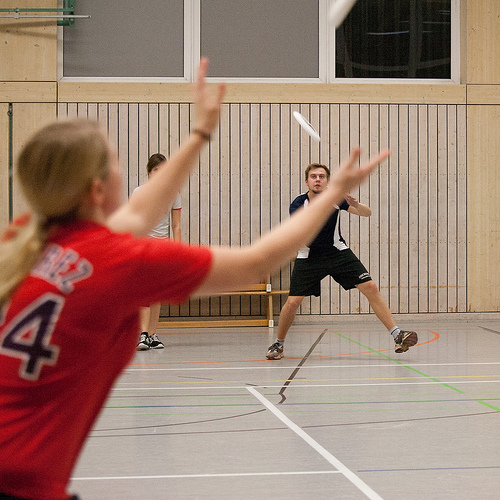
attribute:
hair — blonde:
[59, 188, 80, 195]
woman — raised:
[85, 68, 228, 192]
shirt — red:
[1, 315, 141, 421]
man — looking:
[296, 156, 336, 199]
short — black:
[279, 247, 356, 303]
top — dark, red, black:
[316, 199, 348, 253]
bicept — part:
[356, 183, 381, 213]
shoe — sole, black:
[408, 326, 418, 351]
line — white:
[261, 382, 293, 434]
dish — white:
[291, 101, 325, 149]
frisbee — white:
[308, 104, 329, 126]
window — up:
[170, 12, 359, 86]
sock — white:
[390, 319, 408, 333]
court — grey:
[280, 351, 488, 498]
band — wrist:
[340, 187, 369, 217]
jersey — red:
[35, 223, 134, 413]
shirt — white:
[151, 195, 183, 251]